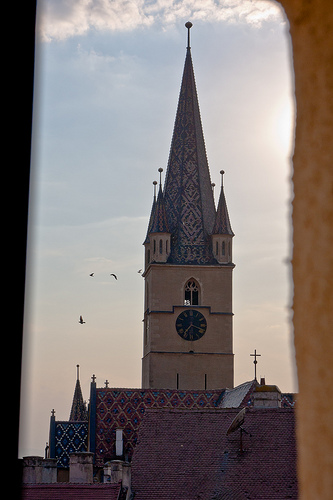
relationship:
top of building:
[122, 23, 258, 272] [36, 21, 261, 467]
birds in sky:
[62, 259, 124, 344] [36, 28, 135, 365]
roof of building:
[92, 379, 276, 455] [36, 21, 261, 467]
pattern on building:
[102, 394, 138, 453] [36, 21, 261, 467]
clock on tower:
[174, 305, 210, 345] [137, 38, 233, 385]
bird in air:
[70, 302, 95, 338] [31, 224, 145, 341]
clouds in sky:
[36, 2, 273, 57] [36, 28, 135, 365]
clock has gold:
[174, 305, 210, 345] [177, 310, 203, 321]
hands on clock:
[183, 324, 201, 347] [174, 305, 210, 345]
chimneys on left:
[25, 448, 130, 499] [0, 8, 81, 479]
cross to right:
[246, 346, 261, 389] [305, 37, 328, 498]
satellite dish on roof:
[223, 407, 256, 465] [92, 379, 276, 455]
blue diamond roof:
[48, 410, 87, 475] [36, 408, 111, 482]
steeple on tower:
[165, 13, 215, 256] [137, 38, 233, 385]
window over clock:
[176, 268, 210, 309] [174, 305, 210, 345]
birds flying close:
[62, 259, 124, 344] [88, 273, 111, 283]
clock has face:
[174, 305, 210, 345] [179, 313, 202, 338]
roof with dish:
[138, 409, 292, 489] [220, 405, 261, 431]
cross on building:
[42, 404, 62, 421] [36, 408, 111, 482]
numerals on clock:
[173, 314, 188, 334] [174, 305, 210, 345]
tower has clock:
[137, 38, 233, 385] [174, 305, 210, 345]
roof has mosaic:
[92, 379, 276, 455] [100, 390, 221, 421]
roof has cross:
[36, 408, 111, 482] [42, 404, 62, 421]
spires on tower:
[129, 166, 254, 265] [137, 38, 233, 385]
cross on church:
[246, 346, 261, 389] [72, 268, 287, 474]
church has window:
[72, 268, 287, 474] [176, 268, 210, 309]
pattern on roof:
[102, 394, 138, 453] [92, 379, 276, 455]